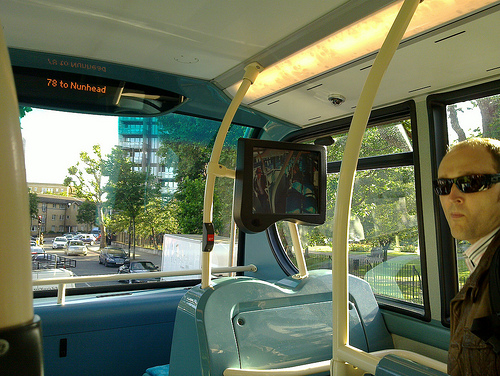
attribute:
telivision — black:
[228, 138, 331, 223]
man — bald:
[432, 138, 497, 373]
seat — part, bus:
[180, 251, 342, 374]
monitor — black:
[245, 137, 332, 233]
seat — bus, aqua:
[200, 267, 397, 362]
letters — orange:
[26, 66, 134, 106]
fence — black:
[348, 256, 425, 306]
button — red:
[199, 231, 219, 247]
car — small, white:
[51, 234, 68, 250]